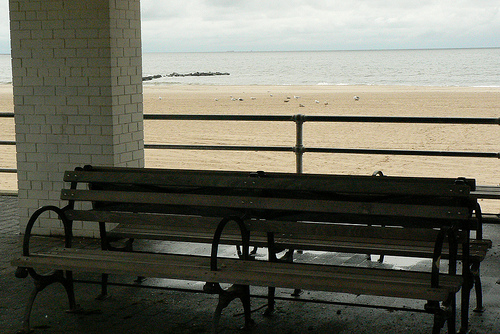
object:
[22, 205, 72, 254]
metal bars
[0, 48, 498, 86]
ocean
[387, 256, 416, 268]
water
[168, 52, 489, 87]
water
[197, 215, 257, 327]
bar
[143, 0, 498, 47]
cloud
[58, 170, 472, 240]
wooden slats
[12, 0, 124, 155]
support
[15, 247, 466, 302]
planks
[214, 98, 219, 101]
seagulls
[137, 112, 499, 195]
railing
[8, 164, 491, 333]
wooden bench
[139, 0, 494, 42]
sky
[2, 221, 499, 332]
brick floor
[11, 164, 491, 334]
bench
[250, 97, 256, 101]
birds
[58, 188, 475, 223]
slate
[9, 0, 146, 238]
brick wall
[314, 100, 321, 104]
bird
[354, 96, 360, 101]
seagull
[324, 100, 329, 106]
seagull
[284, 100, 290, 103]
seagull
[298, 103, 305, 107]
seagull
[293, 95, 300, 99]
seagull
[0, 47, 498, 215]
beach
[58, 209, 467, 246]
slate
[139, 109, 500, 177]
bars/railing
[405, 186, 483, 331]
arm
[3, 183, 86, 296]
arm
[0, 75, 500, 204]
sand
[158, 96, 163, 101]
seagulls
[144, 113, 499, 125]
bars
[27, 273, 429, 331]
concrete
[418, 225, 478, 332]
bar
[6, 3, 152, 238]
bricks